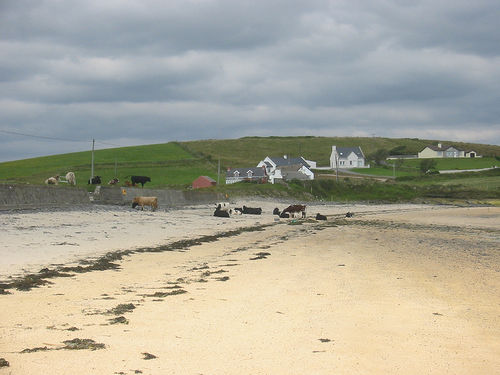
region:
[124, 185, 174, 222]
this is a cow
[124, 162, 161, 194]
this is a cow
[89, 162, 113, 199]
this is a cow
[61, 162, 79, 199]
this is a cow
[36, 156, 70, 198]
this is a cow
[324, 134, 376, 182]
this is a house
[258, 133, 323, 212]
this is a house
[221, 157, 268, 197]
this is a house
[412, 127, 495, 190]
this is a house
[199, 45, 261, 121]
this is a cloud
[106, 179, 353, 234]
cows in the field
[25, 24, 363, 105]
the sky is cloudy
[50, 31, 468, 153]
the sky is cloudy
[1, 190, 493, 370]
a beach area at low tide.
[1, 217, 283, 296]
seaweed left on the beach during low tide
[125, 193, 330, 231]
cows on the beach from the nearby farm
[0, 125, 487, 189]
three homes on a grassy hill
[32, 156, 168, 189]
cows grazing in a grassy field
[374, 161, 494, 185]
portion of a street in a rural area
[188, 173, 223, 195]
red outbuilding on a farm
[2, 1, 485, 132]
dark gray heavily clouded sky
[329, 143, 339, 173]
chimney on the side of a home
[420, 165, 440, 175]
car driving down a rural road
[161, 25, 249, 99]
a bunch of grey clouds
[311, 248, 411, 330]
a bunch of beach sand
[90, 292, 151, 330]
a bunch of washed up seaweed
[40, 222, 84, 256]
the still waves of the ocean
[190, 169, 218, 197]
a small red house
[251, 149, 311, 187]
a big white house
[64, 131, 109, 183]
a large grey telephone pole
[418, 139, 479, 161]
a big house with a brown roof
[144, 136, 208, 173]
a large green grassy hill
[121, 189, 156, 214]
a big brown horse drinking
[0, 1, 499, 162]
a cloudy sky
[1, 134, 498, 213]
a rounded green hill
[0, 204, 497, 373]
a sandy beach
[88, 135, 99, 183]
a wooden utility pole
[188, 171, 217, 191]
a red barn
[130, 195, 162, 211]
a brown cow on the sand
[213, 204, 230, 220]
a black cow laying down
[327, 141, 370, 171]
a small white house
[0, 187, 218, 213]
a concrete wall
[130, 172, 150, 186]
a black cow in the field